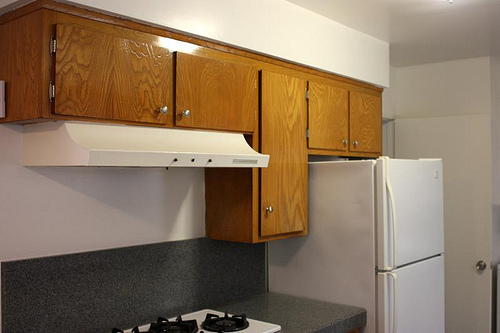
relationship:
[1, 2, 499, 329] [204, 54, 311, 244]
kitchen has cabinet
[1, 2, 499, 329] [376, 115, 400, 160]
kitchen has air vent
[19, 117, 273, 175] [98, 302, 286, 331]
air vent above stovetop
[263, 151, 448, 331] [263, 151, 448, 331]
refrigerator has refrigerator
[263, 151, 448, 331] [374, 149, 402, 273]
refrigerator has handle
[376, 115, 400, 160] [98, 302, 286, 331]
air vent over stovetop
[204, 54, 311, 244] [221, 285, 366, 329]
cabinet over countertop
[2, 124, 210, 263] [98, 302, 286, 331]
wall behind stovetop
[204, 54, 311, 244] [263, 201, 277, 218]
cabinet has knob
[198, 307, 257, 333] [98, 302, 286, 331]
burner on top of stovetop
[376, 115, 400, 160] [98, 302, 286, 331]
air vent on top of stovetop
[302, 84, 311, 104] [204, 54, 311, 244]
hinge on side of cabinet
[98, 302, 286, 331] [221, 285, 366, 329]
stovetop on surface of countertop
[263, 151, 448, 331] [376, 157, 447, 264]
refrigerator has door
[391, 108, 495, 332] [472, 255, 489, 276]
door has knob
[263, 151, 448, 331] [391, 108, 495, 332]
refrigerator has door